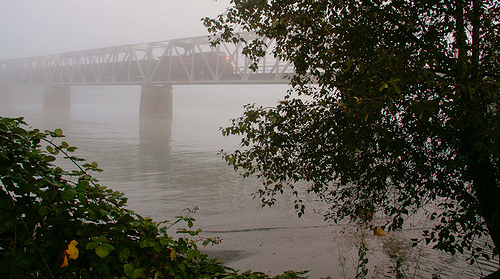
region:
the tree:
[331, 66, 444, 138]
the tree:
[353, 111, 401, 154]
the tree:
[421, 28, 455, 122]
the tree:
[406, 96, 450, 136]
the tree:
[394, 119, 463, 236]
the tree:
[351, 166, 412, 244]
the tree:
[401, 114, 431, 152]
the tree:
[382, 53, 449, 148]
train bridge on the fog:
[14, 39, 310, 151]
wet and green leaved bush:
[11, 116, 191, 277]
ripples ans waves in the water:
[179, 153, 234, 228]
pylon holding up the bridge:
[131, 93, 184, 153]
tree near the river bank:
[229, 25, 488, 242]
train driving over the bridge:
[29, 51, 260, 86]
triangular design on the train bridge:
[116, 39, 271, 92]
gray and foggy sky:
[14, 9, 86, 34]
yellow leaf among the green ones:
[54, 234, 89, 270]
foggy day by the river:
[22, 22, 376, 242]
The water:
[236, 193, 278, 250]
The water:
[260, 189, 321, 260]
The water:
[269, 242, 291, 270]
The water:
[283, 205, 330, 271]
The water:
[265, 220, 294, 272]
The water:
[267, 251, 287, 273]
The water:
[245, 186, 285, 268]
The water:
[281, 219, 313, 276]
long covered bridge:
[5, 29, 325, 99]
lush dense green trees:
[196, 0, 498, 260]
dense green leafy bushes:
[10, 110, 210, 277]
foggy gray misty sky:
[1, 2, 296, 58]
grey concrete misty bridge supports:
[31, 80, 185, 127]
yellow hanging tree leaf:
[365, 217, 393, 245]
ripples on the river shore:
[179, 222, 496, 277]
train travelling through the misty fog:
[1, 51, 253, 92]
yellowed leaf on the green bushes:
[53, 237, 86, 277]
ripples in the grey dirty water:
[57, 96, 236, 209]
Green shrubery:
[0, 115, 187, 275]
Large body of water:
[35, 105, 427, 225]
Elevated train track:
[0, 56, 351, 136]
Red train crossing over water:
[7, 55, 307, 83]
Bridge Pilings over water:
[8, 53, 333, 134]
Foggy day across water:
[0, 1, 93, 83]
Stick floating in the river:
[173, 216, 373, 236]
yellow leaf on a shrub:
[56, 238, 78, 263]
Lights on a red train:
[168, 51, 239, 77]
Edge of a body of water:
[206, 248, 436, 276]